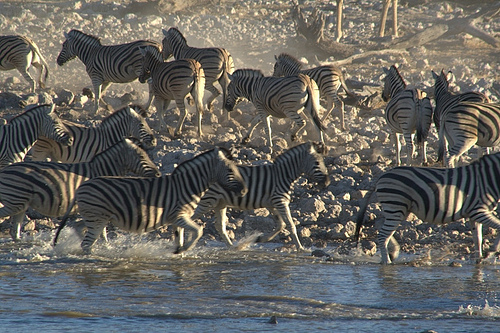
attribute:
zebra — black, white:
[226, 65, 332, 141]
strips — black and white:
[102, 186, 169, 217]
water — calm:
[23, 261, 165, 315]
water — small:
[63, 250, 371, 329]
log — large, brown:
[294, 20, 442, 65]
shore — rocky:
[284, 188, 392, 259]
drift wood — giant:
[303, 11, 487, 81]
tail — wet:
[347, 191, 378, 245]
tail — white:
[188, 73, 213, 117]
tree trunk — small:
[328, 3, 351, 52]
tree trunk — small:
[373, 0, 394, 38]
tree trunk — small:
[388, 0, 406, 42]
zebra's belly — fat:
[396, 186, 463, 231]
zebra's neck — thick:
[9, 112, 44, 165]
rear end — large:
[171, 57, 211, 101]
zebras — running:
[18, 53, 497, 275]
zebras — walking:
[9, 72, 492, 239]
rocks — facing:
[304, 187, 357, 232]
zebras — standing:
[16, 109, 490, 270]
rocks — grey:
[295, 180, 375, 220]